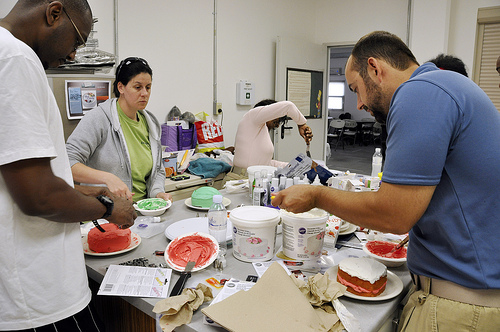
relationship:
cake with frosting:
[335, 254, 390, 302] [339, 257, 387, 285]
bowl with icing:
[132, 187, 174, 218] [138, 196, 164, 209]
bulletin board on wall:
[284, 63, 324, 118] [2, 5, 314, 170]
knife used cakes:
[301, 140, 321, 158] [323, 230, 395, 299]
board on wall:
[41, 62, 114, 140] [106, 4, 355, 178]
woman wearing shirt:
[233, 98, 315, 176] [235, 96, 313, 176]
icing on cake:
[189, 181, 215, 205] [194, 181, 216, 206]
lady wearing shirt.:
[64, 55, 172, 217] [75, 98, 158, 205]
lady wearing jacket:
[64, 55, 172, 217] [71, 90, 166, 218]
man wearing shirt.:
[270, 25, 497, 330] [0, 28, 97, 318]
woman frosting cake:
[231, 91, 323, 174] [293, 150, 341, 182]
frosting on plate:
[162, 234, 221, 268] [166, 231, 224, 270]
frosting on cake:
[356, 260, 381, 275] [314, 243, 398, 300]